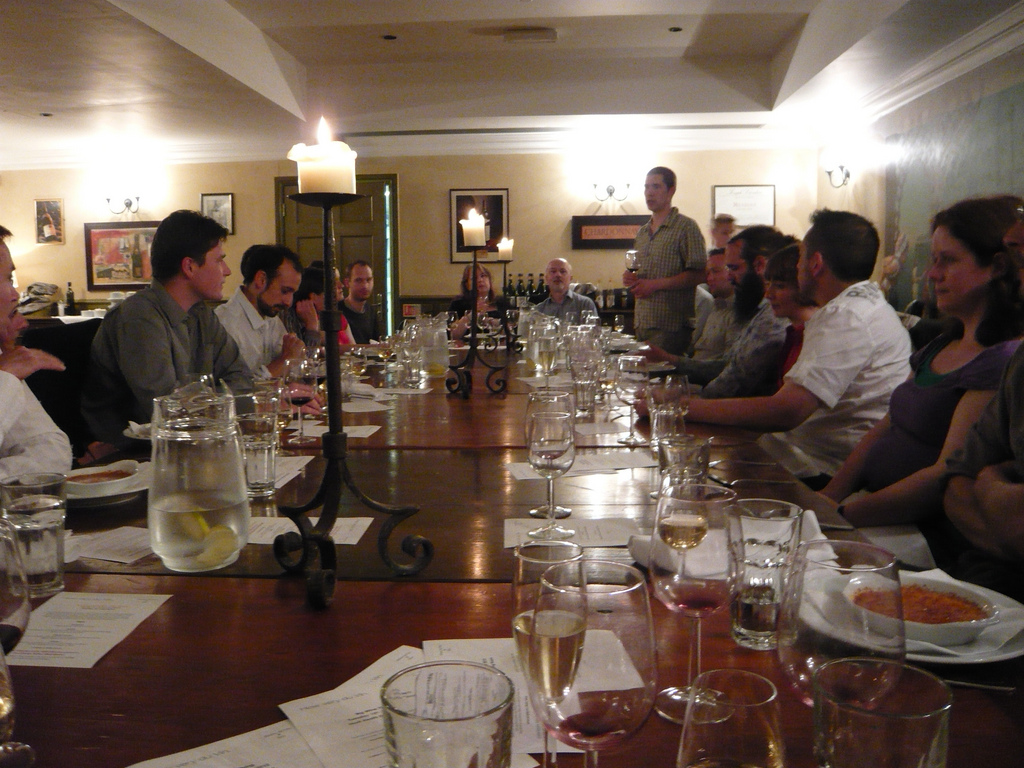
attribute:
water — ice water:
[156, 428, 245, 567]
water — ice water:
[152, 419, 246, 566]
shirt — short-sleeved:
[761, 279, 911, 489]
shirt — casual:
[91, 285, 260, 417]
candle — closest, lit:
[286, 108, 360, 195]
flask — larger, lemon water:
[148, 369, 246, 571]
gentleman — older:
[528, 251, 598, 323]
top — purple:
[873, 324, 1005, 508]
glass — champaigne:
[655, 475, 710, 609]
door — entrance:
[279, 177, 398, 342]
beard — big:
[725, 266, 762, 321]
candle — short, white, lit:
[288, 104, 369, 200]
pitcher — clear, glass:
[142, 369, 256, 581]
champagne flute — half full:
[513, 539, 588, 765]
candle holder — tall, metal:
[266, 184, 440, 615]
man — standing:
[620, 166, 715, 346]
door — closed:
[266, 168, 401, 310]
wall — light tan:
[11, 126, 900, 289]